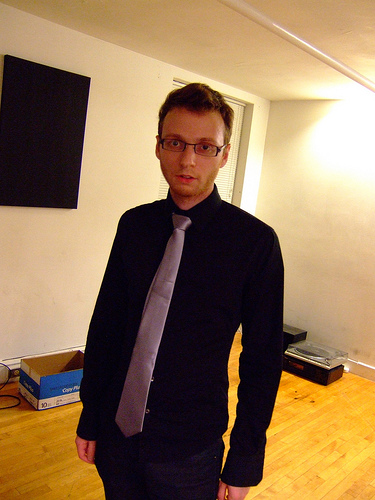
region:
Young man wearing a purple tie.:
[72, 82, 285, 498]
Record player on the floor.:
[285, 337, 351, 384]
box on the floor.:
[15, 347, 84, 411]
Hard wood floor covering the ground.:
[0, 331, 373, 499]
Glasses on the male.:
[148, 82, 240, 200]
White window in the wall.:
[143, 64, 267, 226]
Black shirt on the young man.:
[68, 64, 274, 488]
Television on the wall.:
[1, 51, 91, 216]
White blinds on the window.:
[171, 79, 243, 202]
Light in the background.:
[313, 82, 373, 170]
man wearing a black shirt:
[70, 68, 297, 498]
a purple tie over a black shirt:
[112, 200, 198, 438]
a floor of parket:
[277, 378, 372, 496]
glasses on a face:
[151, 130, 231, 160]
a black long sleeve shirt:
[69, 194, 289, 491]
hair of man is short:
[99, 70, 285, 274]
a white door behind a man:
[148, 71, 259, 352]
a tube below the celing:
[233, 2, 373, 97]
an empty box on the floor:
[10, 342, 95, 414]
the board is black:
[2, 53, 97, 218]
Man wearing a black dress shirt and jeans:
[72, 81, 286, 498]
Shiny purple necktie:
[114, 212, 191, 437]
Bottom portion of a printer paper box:
[16, 348, 91, 410]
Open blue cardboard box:
[16, 349, 94, 411]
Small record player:
[281, 340, 347, 384]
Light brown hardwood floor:
[1, 331, 373, 498]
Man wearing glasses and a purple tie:
[68, 80, 288, 499]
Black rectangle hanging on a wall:
[0, 53, 92, 209]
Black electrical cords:
[0, 361, 21, 411]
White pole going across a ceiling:
[221, 0, 373, 95]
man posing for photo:
[76, 84, 279, 498]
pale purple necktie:
[111, 213, 197, 438]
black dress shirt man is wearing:
[70, 188, 284, 480]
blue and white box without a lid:
[17, 350, 87, 414]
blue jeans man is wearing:
[88, 442, 226, 498]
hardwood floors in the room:
[2, 317, 374, 498]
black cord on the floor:
[0, 366, 19, 415]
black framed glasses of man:
[153, 131, 226, 159]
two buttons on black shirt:
[141, 371, 155, 414]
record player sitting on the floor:
[282, 337, 351, 391]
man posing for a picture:
[25, 68, 349, 488]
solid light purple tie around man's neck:
[111, 189, 197, 444]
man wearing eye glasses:
[144, 84, 232, 202]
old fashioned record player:
[279, 323, 349, 386]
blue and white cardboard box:
[16, 341, 92, 419]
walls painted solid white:
[9, 217, 84, 342]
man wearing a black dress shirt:
[61, 187, 297, 465]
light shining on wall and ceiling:
[305, 60, 373, 228]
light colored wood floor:
[18, 336, 371, 492]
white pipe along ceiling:
[213, 0, 373, 100]